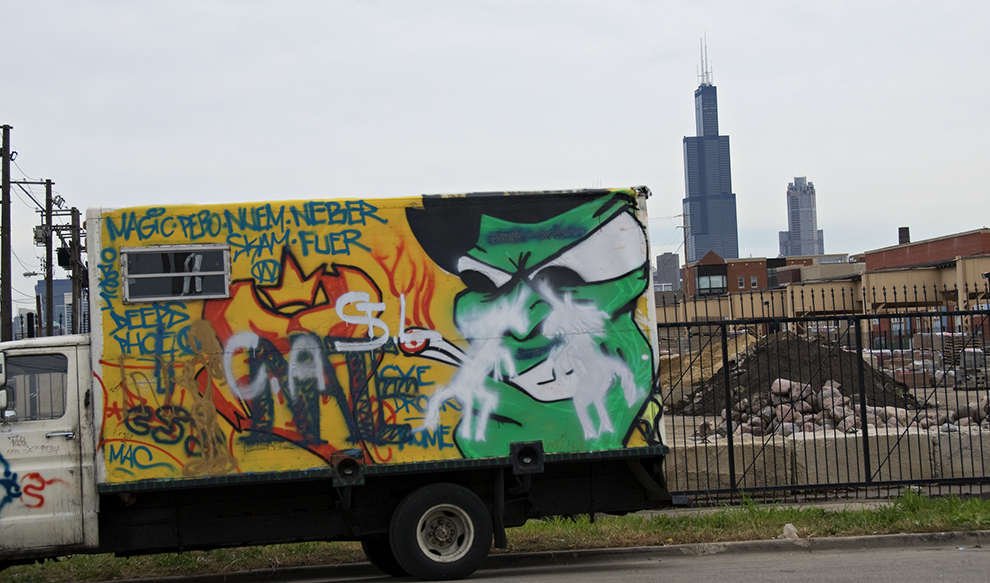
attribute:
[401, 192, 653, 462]
face — green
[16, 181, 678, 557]
truck — yellow, white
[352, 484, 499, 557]
wheels — back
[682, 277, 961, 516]
gate — black, steel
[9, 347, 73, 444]
window — driver's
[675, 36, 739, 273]
building — tall, skyscraper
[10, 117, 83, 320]
poles — powerline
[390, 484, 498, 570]
tire — black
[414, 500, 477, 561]
rim — white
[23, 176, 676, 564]
van — spray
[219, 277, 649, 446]
paint — white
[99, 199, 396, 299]
letters — blue, painted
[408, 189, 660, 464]
ghost — large, green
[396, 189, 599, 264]
hair — black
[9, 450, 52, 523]
writing — blue, orange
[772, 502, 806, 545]
trash — small piece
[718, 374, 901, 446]
rocks — mound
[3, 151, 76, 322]
poles — group, long, brown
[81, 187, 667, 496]
sign — yellow, green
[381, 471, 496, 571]
tire — black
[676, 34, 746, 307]
tower — grey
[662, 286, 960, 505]
fence — black, iron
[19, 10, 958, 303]
sky — grey, white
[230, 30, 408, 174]
clouds — white